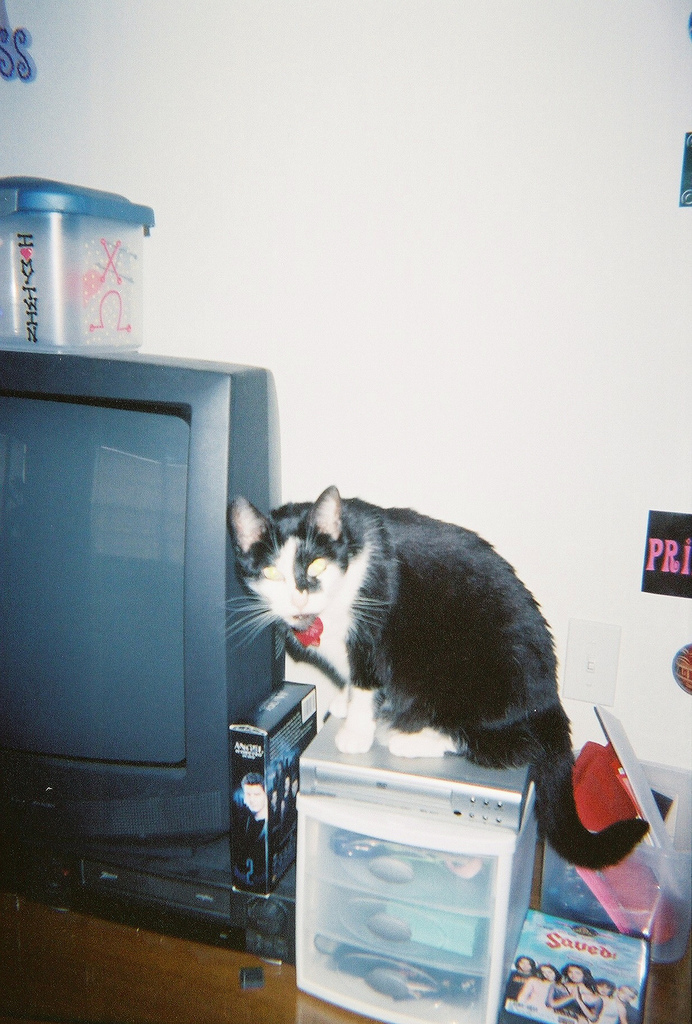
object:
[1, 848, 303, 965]
vcr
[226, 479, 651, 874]
cat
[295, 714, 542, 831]
dvd player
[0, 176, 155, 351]
container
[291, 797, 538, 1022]
drawers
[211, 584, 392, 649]
whiskers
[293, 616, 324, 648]
tag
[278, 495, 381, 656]
neck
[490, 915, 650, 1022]
dvd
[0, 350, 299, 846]
television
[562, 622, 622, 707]
jack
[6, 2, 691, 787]
wall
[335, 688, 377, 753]
paw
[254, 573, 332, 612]
face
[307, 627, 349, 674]
chest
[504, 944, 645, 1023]
dvd cover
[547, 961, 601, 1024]
people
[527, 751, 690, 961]
container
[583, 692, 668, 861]
lid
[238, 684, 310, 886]
cassette tape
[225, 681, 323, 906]
box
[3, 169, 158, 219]
lid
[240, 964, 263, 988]
dust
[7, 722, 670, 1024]
floor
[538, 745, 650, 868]
tail